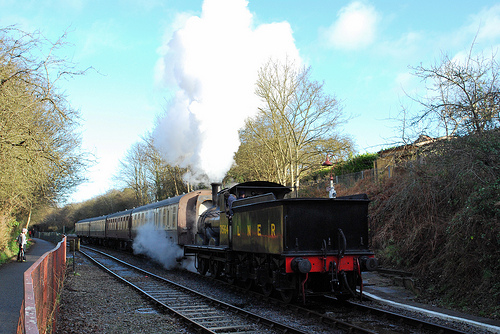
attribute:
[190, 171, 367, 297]
front car — black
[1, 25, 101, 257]
tree — wild 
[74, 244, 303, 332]
tracks — empty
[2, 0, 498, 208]
sky — clear , blue, bright blue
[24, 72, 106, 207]
leaves — green 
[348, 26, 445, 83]
clouds — white 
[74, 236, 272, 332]
tracks — parallel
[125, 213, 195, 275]
smoke — blast 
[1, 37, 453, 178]
sky — blue 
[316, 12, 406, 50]
clouds — white 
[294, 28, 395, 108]
sky — blue 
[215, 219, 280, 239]
writing — yellow 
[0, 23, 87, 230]
leaves — dead 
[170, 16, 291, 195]
steam — thick , white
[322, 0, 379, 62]
cloud — white, small 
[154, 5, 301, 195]
smoke — white 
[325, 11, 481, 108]
clouds — white 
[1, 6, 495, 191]
sky — blue